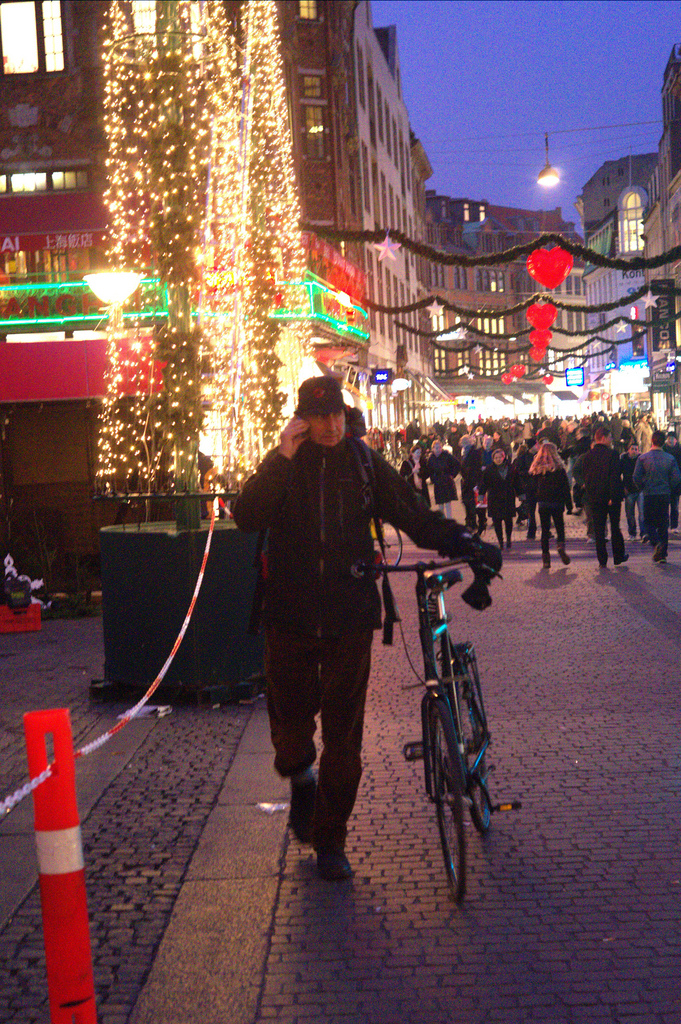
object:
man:
[232, 375, 502, 879]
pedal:
[498, 800, 522, 811]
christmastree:
[90, 0, 322, 492]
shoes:
[318, 843, 352, 879]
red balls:
[526, 302, 558, 359]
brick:
[292, 887, 298, 893]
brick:
[324, 892, 339, 916]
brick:
[365, 844, 384, 871]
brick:
[388, 876, 408, 893]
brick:
[404, 906, 424, 936]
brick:
[389, 937, 414, 957]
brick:
[308, 958, 325, 978]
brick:
[101, 925, 119, 950]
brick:
[93, 914, 118, 964]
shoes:
[287, 766, 317, 842]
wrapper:
[255, 802, 289, 815]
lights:
[92, 0, 326, 490]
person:
[526, 443, 573, 569]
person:
[583, 427, 629, 569]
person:
[458, 433, 481, 528]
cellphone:
[298, 413, 302, 437]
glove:
[461, 536, 502, 610]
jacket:
[233, 440, 463, 638]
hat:
[293, 375, 346, 416]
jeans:
[539, 507, 565, 554]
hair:
[527, 441, 565, 476]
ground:
[0, 501, 681, 1022]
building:
[0, 0, 681, 603]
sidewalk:
[0, 514, 681, 1024]